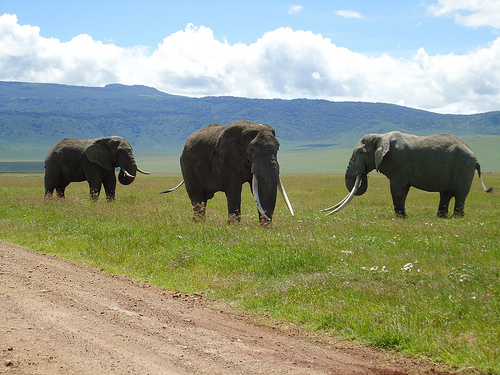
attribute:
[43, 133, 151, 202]
elephant — walking, brown, grey, big, standing, large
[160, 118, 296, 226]
elephant — walking, brown, grey, big, standing, large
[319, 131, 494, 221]
elephant — walking, brown, grey, big, standing, large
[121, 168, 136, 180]
tusk — ivory, white, short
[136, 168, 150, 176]
tusk — ivory, white, short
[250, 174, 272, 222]
tusk — ivory, white, long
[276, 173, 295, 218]
tusk — ivory, white, long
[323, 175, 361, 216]
tusk — ivory, white, long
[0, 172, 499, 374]
grass — green, flowery, light green, long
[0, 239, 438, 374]
road — dirt, muddy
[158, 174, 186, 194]
tail — curly, moving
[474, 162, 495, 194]
tail — curly, moving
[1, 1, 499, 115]
sky — clear, blue, cloudy, light blue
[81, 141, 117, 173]
ear — large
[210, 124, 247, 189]
ear — large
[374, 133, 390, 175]
ear — large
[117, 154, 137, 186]
trunk — long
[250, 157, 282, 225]
trunk — long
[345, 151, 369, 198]
trunk — long